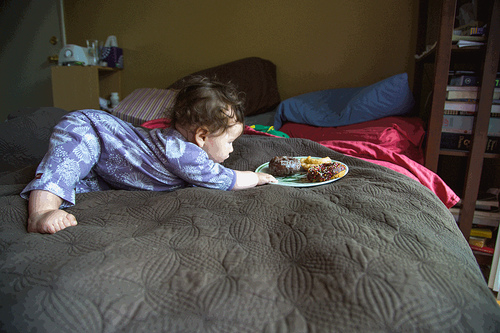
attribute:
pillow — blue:
[249, 72, 419, 137]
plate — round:
[253, 150, 348, 187]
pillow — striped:
[106, 80, 181, 129]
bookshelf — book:
[413, 0, 499, 265]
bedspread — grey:
[6, 135, 499, 329]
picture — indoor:
[1, 0, 498, 332]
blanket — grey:
[273, 191, 458, 329]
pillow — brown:
[176, 46, 316, 144]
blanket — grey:
[93, 193, 455, 325]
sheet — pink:
[138, 100, 467, 222]